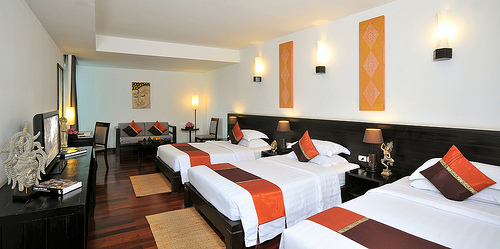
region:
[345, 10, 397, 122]
Orange and white wall hanging.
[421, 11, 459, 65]
Bright light on the wall.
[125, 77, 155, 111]
Picture above the couch.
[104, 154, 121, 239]
Dark brown hard wood floor.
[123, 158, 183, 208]
Rug on the wood floor.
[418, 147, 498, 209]
Orange and brown pillow on the bed.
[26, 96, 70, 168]
Television on the stand.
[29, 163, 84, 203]
Book on the stand.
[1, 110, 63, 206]
Art object on the stand.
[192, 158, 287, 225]
Orange and brown bed spread.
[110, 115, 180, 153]
Gray sofa on the end of the room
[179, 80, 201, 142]
Stand lamp shades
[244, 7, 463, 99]
Three lamps on the wall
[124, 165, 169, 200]
brown carpets on the floor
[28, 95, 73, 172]
Television in the TV stand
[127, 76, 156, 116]
face painting on the wall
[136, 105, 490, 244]
Three Queen size beds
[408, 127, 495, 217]
orange and brown decorative pillow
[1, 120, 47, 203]
glass decoration on the stand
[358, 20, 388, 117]
orange wall decoration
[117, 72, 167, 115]
a picture on the wall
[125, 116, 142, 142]
a pillow on the couch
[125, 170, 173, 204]
a rug on the floor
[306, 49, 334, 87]
a light hanging on the wall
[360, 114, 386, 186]
a lamp on a table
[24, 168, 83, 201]
a book on the table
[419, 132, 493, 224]
a pillow on the bed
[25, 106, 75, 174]
a televsion one the stand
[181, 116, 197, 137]
flowers on a table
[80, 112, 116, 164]
a chair at the desk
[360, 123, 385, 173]
a brown table lamp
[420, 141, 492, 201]
a decorative pillow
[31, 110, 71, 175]
a large black t.v.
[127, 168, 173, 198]
a brown area rug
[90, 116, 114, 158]
a brown chair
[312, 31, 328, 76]
a tall wall light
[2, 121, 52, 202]
a white sculpture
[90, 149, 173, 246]
part of a brown hardwood floor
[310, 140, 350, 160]
part of a white pillow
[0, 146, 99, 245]
a black t.v. cabinet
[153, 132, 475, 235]
three beds in a room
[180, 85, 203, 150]
a tall floor lamp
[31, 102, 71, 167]
a flat screen tv on a dresser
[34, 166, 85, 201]
a book on a dresser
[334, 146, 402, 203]
a small black table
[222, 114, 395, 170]
three small lamps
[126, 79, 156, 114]
a picture hanging on the wall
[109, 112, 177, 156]
a grey couch with two pillows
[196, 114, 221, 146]
a wood chair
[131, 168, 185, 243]
two rugs on the floor